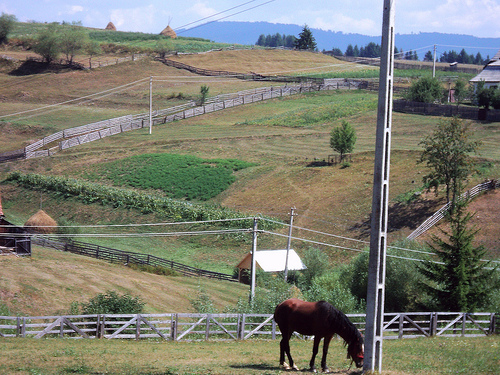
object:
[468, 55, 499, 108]
small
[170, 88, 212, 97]
bush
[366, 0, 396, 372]
pole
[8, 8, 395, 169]
this is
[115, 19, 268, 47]
wires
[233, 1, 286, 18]
sky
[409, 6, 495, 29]
clouds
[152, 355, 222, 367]
grass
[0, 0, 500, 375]
field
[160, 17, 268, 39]
power lines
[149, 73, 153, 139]
poles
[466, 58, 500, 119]
building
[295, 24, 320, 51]
evergreen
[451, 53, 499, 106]
distance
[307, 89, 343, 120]
patch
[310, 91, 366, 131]
greenery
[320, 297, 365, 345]
mane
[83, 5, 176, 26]
white clouds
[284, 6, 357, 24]
blue sky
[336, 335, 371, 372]
grazing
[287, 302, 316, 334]
brown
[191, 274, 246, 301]
short green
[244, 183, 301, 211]
brown grass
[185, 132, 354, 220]
green and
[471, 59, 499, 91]
yellow roof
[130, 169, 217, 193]
green vegetation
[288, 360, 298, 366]
white hooves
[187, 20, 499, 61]
mountains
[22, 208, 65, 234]
bale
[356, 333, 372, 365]
white marking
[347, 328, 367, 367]
horse's head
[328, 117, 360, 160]
pine tree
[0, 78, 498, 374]
open pasture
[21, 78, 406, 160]
corral fences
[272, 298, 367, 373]
animals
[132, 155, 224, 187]
grass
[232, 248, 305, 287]
house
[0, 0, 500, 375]
farmland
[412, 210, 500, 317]
evergreen tree